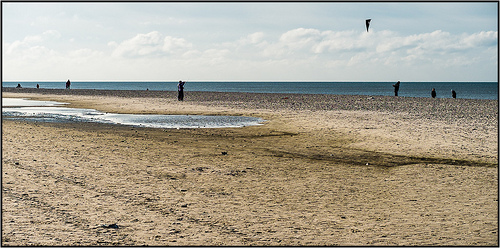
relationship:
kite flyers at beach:
[392, 81, 401, 96] [3, 88, 495, 243]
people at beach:
[430, 88, 436, 99] [3, 88, 495, 243]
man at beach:
[177, 80, 186, 102] [3, 88, 495, 243]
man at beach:
[66, 79, 71, 89] [3, 88, 495, 243]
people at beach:
[36, 83, 39, 89] [3, 88, 495, 243]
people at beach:
[15, 83, 22, 88] [3, 88, 495, 243]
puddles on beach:
[2, 96, 269, 129] [3, 88, 495, 243]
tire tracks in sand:
[2, 160, 254, 245] [3, 89, 497, 246]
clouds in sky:
[2, 5, 496, 84] [2, 2, 499, 80]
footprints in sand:
[82, 144, 262, 244] [3, 89, 497, 246]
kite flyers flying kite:
[392, 81, 401, 96] [364, 18, 372, 31]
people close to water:
[431, 84, 459, 98] [3, 80, 495, 98]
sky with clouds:
[2, 2, 499, 80] [2, 5, 496, 84]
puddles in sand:
[7, 93, 269, 133] [3, 89, 497, 246]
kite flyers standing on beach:
[392, 81, 401, 96] [3, 88, 495, 243]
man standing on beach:
[177, 80, 186, 102] [3, 88, 495, 243]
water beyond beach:
[6, 78, 499, 102] [3, 88, 495, 243]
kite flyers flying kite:
[392, 81, 401, 96] [362, 14, 372, 35]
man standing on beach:
[64, 75, 74, 93] [3, 88, 495, 243]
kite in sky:
[364, 14, 373, 34] [2, 2, 499, 80]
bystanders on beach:
[419, 80, 467, 102] [3, 88, 495, 243]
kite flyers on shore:
[387, 80, 462, 98] [7, 100, 497, 115]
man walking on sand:
[66, 79, 71, 89] [5, 88, 495, 126]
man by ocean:
[66, 79, 71, 89] [1, 80, 498, 105]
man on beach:
[175, 78, 185, 100] [4, 84, 497, 104]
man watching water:
[175, 78, 185, 100] [4, 81, 499, 100]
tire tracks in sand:
[2, 160, 254, 245] [2, 116, 316, 244]